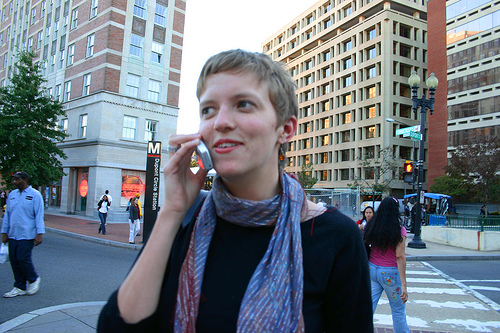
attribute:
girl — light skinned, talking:
[97, 48, 374, 332]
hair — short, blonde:
[195, 48, 299, 171]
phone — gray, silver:
[198, 139, 214, 170]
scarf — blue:
[175, 174, 305, 331]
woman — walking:
[363, 198, 409, 330]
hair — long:
[364, 196, 401, 254]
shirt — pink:
[367, 226, 408, 266]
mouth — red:
[211, 139, 244, 153]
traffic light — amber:
[405, 160, 413, 172]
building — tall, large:
[2, 1, 186, 225]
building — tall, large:
[262, 1, 446, 201]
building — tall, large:
[445, 0, 499, 183]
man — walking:
[2, 171, 46, 299]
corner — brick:
[44, 212, 143, 251]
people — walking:
[98, 188, 141, 245]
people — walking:
[352, 196, 412, 330]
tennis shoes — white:
[2, 276, 40, 299]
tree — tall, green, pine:
[2, 45, 70, 188]